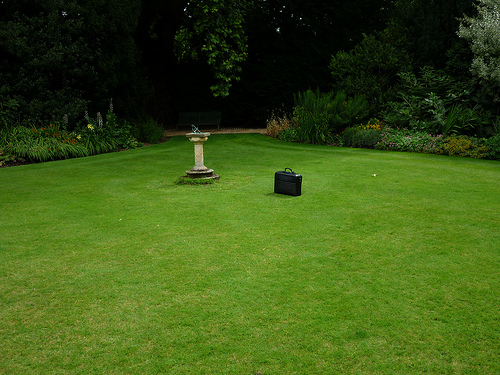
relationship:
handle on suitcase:
[281, 167, 295, 172] [274, 167, 301, 196]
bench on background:
[170, 111, 224, 131] [5, 99, 487, 159]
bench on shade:
[158, 103, 244, 125] [58, 90, 369, 130]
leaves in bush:
[387, 128, 469, 155] [253, 99, 493, 166]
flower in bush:
[87, 122, 97, 131] [1, 122, 141, 159]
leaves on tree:
[201, 20, 232, 60] [171, 0, 250, 98]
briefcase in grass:
[273, 167, 302, 196] [334, 173, 482, 335]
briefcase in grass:
[266, 166, 311, 207] [2, 132, 498, 372]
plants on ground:
[265, 2, 499, 159] [1, 125, 499, 372]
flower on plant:
[86, 120, 96, 131] [4, 95, 149, 175]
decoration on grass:
[179, 130, 220, 183] [2, 132, 498, 372]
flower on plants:
[87, 122, 97, 131] [9, 112, 134, 171]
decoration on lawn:
[178, 124, 220, 183] [12, 158, 464, 371]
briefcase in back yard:
[273, 167, 302, 196] [96, 133, 404, 311]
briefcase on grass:
[273, 167, 302, 196] [2, 132, 498, 372]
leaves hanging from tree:
[8, 6, 498, 163] [161, 12, 278, 140]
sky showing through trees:
[271, 5, 306, 38] [138, 3, 390, 130]